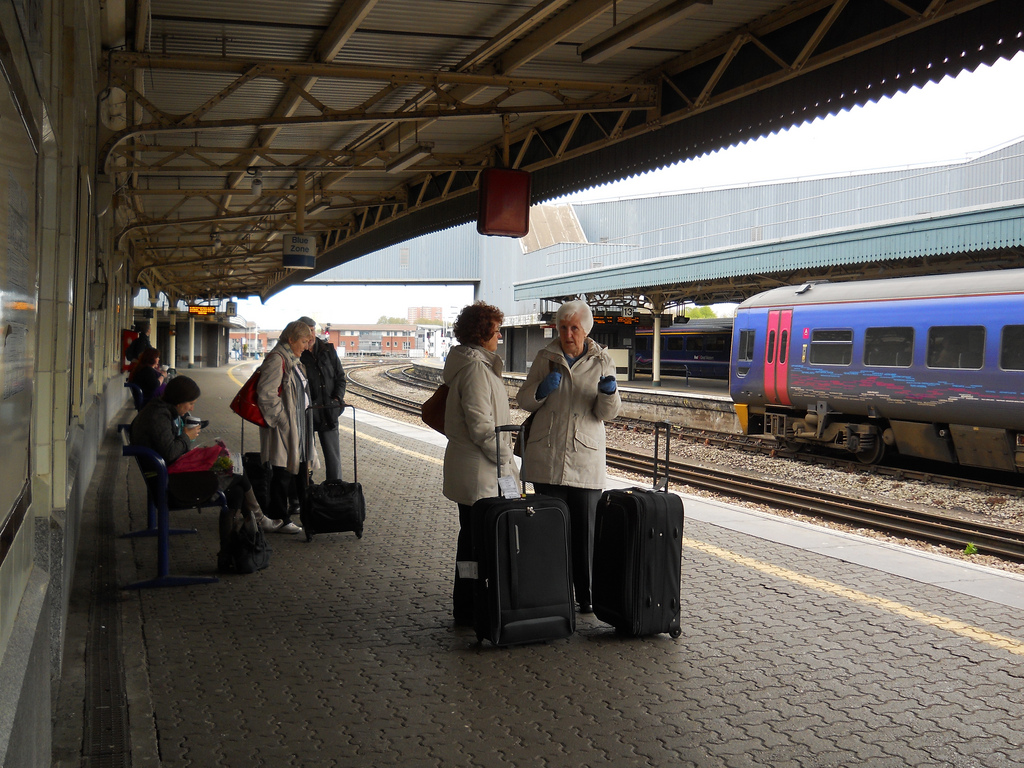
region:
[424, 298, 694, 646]
Two women standing with luggage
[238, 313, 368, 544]
woman and man standing near luggage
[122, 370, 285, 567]
person sitting on a bench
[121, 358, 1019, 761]
a brown brick sidewalk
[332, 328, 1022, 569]
a set of empty railroad tracks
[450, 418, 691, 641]
two black suitcases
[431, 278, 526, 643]
woman in a white coat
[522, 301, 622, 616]
woman wearing a white jacket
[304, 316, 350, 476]
man in a black coat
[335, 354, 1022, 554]
unused train tracks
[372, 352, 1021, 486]
train tracks the train is on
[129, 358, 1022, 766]
platform next to the tracks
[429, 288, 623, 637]
two women wearing beige coats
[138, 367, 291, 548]
person sitting on the bench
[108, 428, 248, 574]
bench on the platform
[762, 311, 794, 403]
red doors on the train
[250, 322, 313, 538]
person standing on train platform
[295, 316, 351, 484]
person standing on train platform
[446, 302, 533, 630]
person standing on train platform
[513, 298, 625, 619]
person standing on train platform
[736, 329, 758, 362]
window on side of train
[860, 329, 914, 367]
window on side of train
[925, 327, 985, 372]
window on side of train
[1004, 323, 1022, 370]
window on side of train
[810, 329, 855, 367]
window on side of train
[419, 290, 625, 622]
two old women talking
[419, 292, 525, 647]
woman with brown curly hair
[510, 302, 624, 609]
woman with white hair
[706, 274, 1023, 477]
train car in blue with red doors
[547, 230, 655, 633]
a person on the sidewalk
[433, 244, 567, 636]
a person on the sidewalk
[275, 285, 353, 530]
a person on the sidewalk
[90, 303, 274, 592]
a person on the sidewalk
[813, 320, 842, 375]
a window ont he train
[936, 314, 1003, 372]
a window ont he train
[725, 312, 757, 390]
a window ont he train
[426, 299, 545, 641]
A person is standing up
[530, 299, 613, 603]
A person is standing up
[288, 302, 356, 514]
A person is standing up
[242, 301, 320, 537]
A person is standing up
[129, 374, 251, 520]
A person is sitting down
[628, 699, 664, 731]
A stone in the floor.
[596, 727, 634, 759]
A stone in the floor.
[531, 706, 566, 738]
A stone in the floor.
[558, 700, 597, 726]
A stone in the floor.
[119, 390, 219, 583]
a blue bench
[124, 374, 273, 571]
a woman sitting on a bench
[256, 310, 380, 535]
two people standing on the platform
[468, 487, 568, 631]
a black suitcase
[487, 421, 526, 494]
the handle on the suitcase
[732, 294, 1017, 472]
a blue and red train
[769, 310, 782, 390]
red doors on the train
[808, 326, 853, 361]
a window on the train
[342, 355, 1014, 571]
brown train tracks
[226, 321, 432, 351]
a red brick building